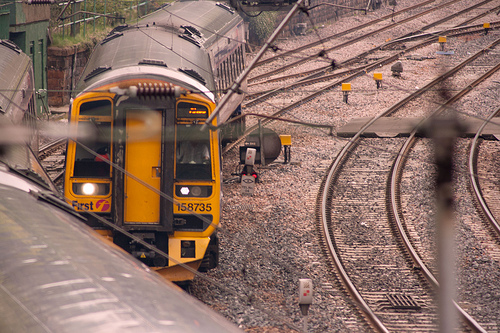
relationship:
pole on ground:
[293, 274, 329, 321] [250, 169, 305, 250]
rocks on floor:
[240, 197, 309, 279] [241, 185, 301, 241]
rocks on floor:
[458, 252, 493, 287] [241, 185, 301, 241]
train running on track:
[55, 0, 250, 295] [220, 1, 496, 196]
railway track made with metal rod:
[313, 76, 471, 322] [298, 162, 343, 247]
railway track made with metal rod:
[241, 0, 488, 90] [355, 48, 393, 56]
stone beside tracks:
[238, 50, 498, 333] [318, 73, 498, 333]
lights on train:
[67, 175, 211, 197] [55, 0, 250, 295]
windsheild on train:
[171, 122, 213, 189] [55, 0, 250, 295]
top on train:
[2, 186, 232, 331] [2, 40, 244, 330]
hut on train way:
[4, 0, 61, 123] [47, 0, 499, 328]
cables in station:
[228, 40, 387, 106] [40, 43, 461, 276]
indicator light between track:
[248, 171, 260, 183] [317, 44, 488, 331]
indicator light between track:
[248, 171, 260, 183] [233, 0, 495, 145]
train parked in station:
[58, 0, 249, 281] [0, 2, 324, 329]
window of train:
[211, 46, 243, 91] [35, 0, 251, 287]